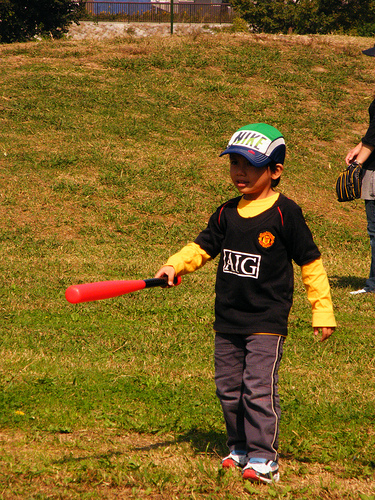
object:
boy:
[153, 121, 338, 484]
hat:
[218, 121, 287, 169]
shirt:
[158, 191, 336, 338]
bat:
[64, 273, 182, 304]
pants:
[213, 320, 286, 465]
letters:
[239, 256, 257, 277]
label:
[257, 231, 275, 249]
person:
[335, 45, 374, 296]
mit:
[334, 157, 364, 202]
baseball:
[0, 0, 374, 499]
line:
[269, 333, 282, 463]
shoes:
[219, 449, 248, 474]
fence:
[68, 2, 232, 25]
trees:
[231, 2, 272, 33]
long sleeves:
[291, 210, 338, 328]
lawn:
[0, 22, 373, 499]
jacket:
[359, 93, 374, 173]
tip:
[241, 468, 257, 480]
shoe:
[239, 457, 279, 487]